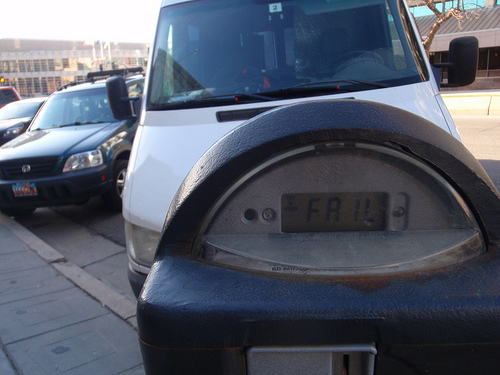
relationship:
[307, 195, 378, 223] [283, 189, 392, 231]
letters on timer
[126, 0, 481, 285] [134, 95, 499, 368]
van behind meter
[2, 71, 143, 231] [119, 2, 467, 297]
truck near van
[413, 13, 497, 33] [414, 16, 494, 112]
brown roof on building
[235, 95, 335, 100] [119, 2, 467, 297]
wiper on van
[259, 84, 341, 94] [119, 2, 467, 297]
wiper on van